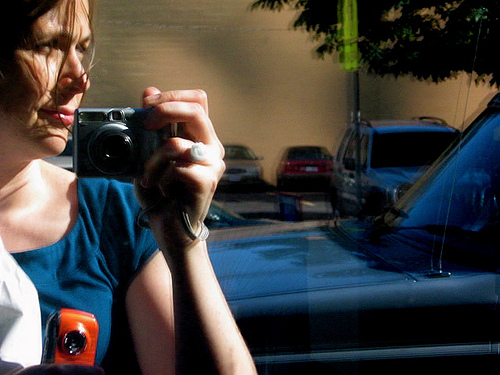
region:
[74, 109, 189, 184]
The camera in the woman's hand.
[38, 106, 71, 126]
The woman's lips.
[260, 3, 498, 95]
The green tress.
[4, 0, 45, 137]
The woman's blonde hair.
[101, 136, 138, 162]
The black camera lens.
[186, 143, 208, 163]
The womans white ring.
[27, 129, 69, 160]
The woman's chin.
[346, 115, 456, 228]
A large parked truck.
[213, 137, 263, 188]
The silver car that is parked.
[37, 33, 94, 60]
The woman's eyes.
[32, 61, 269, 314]
a woman holding a camera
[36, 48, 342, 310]
a woman holding a digital camera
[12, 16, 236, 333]
a woman wearing a shirt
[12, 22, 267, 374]
a woman with brown hair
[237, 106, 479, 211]
vehicles parked on the road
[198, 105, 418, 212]
vehicles parked on the street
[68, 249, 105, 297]
a blue shirt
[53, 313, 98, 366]
an orange camera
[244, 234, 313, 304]
the hood of the car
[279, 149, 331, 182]
a red car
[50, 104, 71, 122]
the womens lips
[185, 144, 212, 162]
a ring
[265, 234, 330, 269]
shadow on the hood of the car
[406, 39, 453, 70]
the leaves on the tree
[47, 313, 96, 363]
woman holds orange camera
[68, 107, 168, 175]
woman holds black camera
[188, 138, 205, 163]
the woman wears a ring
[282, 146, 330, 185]
the red car is parked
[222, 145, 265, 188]
a gray car is parked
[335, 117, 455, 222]
a black car is parked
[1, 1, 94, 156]
the woman has hair on her face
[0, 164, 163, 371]
the woman wears a blue shirt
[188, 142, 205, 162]
the ring she wears is white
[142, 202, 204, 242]
the woman holds camera strap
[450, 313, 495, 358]
part of the black vehicle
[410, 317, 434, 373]
part of the black vehicle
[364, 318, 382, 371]
part of the black vehicle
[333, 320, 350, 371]
part of the black vehicle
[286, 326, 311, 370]
part of the black vehicle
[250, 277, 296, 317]
part of the black vehicle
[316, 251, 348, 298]
part of the black vehicle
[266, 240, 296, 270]
part of the black vehicle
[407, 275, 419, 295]
part of the black vehicle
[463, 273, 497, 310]
part of the black vehicle